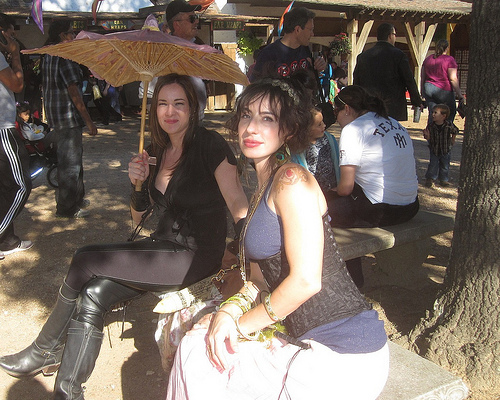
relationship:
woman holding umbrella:
[1, 73, 248, 399] [20, 13, 250, 192]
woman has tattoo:
[165, 80, 388, 400] [271, 164, 308, 200]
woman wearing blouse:
[1, 73, 248, 399] [134, 124, 239, 254]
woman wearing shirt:
[419, 38, 463, 129] [421, 53, 458, 92]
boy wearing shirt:
[421, 104, 459, 187] [427, 121, 460, 156]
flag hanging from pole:
[30, 0, 47, 36] [23, 0, 33, 24]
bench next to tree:
[373, 337, 470, 399] [390, 1, 499, 399]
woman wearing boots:
[1, 73, 248, 399] [0, 283, 104, 399]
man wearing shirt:
[38, 16, 97, 219] [38, 47, 84, 131]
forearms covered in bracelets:
[218, 278, 317, 334] [214, 290, 285, 341]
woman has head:
[1, 73, 248, 399] [152, 71, 198, 134]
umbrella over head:
[20, 13, 250, 192] [152, 71, 198, 134]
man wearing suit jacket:
[353, 23, 422, 122] [351, 40, 421, 122]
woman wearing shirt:
[322, 84, 420, 226] [337, 109, 418, 205]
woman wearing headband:
[165, 80, 388, 400] [243, 79, 300, 106]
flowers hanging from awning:
[326, 29, 353, 60] [262, 1, 472, 22]